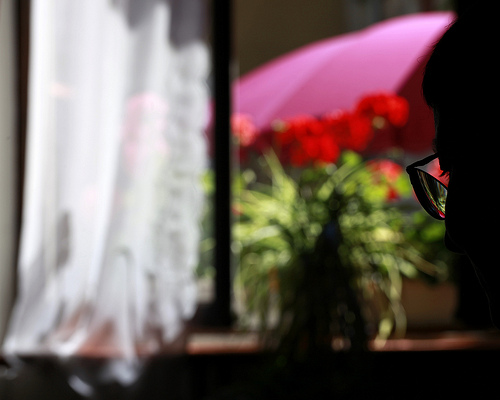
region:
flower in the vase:
[281, 143, 321, 163]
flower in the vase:
[348, 129, 370, 145]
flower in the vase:
[246, 140, 273, 171]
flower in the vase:
[385, 103, 404, 122]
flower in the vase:
[366, 200, 413, 229]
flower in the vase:
[262, 178, 302, 208]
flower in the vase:
[363, 101, 408, 131]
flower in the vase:
[258, 125, 295, 152]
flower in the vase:
[233, 126, 280, 168]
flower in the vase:
[321, 111, 359, 144]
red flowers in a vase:
[235, 95, 442, 170]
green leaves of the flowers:
[241, 170, 431, 266]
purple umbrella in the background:
[247, 7, 461, 117]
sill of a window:
[9, 318, 497, 383]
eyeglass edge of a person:
[403, 149, 459, 226]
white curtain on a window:
[14, 1, 225, 373]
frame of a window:
[195, 6, 262, 327]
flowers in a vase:
[231, 81, 434, 397]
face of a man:
[426, 88, 493, 339]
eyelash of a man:
[432, 163, 449, 183]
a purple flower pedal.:
[233, 4, 457, 124]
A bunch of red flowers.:
[230, 90, 462, 346]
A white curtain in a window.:
[5, 0, 209, 360]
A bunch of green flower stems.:
[235, 144, 475, 349]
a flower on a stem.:
[347, 87, 425, 137]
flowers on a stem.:
[322, 97, 379, 162]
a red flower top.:
[270, 97, 350, 172]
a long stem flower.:
[228, 111, 280, 161]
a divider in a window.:
[203, 0, 246, 335]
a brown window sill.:
[9, 316, 496, 361]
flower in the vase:
[302, 127, 329, 161]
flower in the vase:
[252, 136, 271, 161]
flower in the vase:
[371, 179, 396, 214]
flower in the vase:
[243, 208, 270, 241]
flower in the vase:
[364, 220, 397, 252]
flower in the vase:
[366, 118, 404, 168]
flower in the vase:
[235, 117, 262, 160]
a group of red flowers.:
[205, 90, 499, 175]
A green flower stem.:
[361, 158, 448, 363]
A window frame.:
[175, 0, 255, 335]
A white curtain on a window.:
[0, 0, 218, 395]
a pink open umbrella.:
[212, 18, 460, 163]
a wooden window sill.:
[0, 319, 491, 379]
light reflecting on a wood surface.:
[231, 316, 488, 351]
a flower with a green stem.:
[364, 160, 417, 213]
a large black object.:
[279, 183, 386, 357]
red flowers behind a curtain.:
[104, 96, 173, 184]